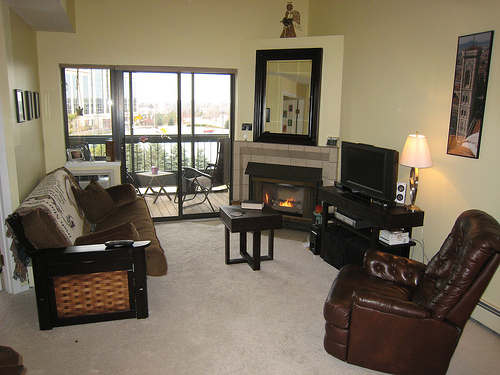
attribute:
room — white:
[0, 2, 488, 370]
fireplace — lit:
[232, 142, 341, 228]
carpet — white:
[0, 217, 498, 371]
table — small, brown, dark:
[220, 199, 285, 272]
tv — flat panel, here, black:
[339, 137, 401, 208]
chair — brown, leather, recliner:
[324, 211, 494, 375]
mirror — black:
[253, 47, 319, 147]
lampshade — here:
[400, 132, 432, 169]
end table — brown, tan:
[28, 241, 151, 330]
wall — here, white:
[245, 34, 345, 144]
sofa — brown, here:
[9, 168, 170, 280]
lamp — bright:
[400, 135, 433, 215]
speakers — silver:
[394, 184, 408, 207]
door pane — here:
[183, 70, 234, 215]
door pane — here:
[120, 62, 180, 225]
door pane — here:
[62, 65, 122, 194]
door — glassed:
[64, 65, 234, 216]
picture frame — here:
[443, 32, 490, 158]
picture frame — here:
[14, 86, 27, 126]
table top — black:
[221, 202, 286, 233]